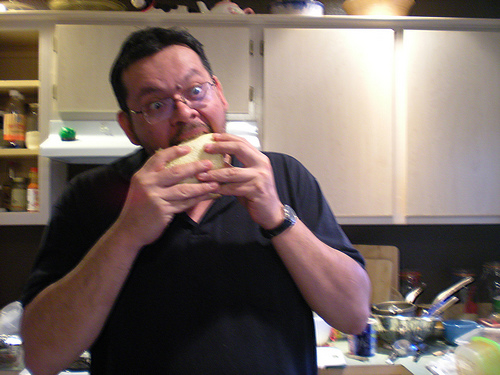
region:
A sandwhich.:
[152, 135, 231, 185]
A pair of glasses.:
[120, 82, 224, 122]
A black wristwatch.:
[261, 202, 299, 247]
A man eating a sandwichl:
[21, 25, 385, 374]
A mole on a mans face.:
[173, 79, 184, 93]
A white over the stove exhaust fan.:
[37, 117, 264, 165]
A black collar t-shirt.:
[24, 145, 366, 373]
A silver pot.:
[371, 280, 425, 315]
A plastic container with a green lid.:
[450, 334, 497, 369]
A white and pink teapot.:
[194, 2, 256, 19]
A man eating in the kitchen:
[6, 10, 493, 363]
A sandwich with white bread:
[160, 132, 230, 194]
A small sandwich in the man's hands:
[137, 124, 279, 206]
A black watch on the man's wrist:
[251, 200, 301, 250]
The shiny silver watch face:
[284, 203, 299, 224]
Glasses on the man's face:
[133, 87, 227, 121]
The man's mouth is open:
[163, 128, 211, 149]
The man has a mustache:
[165, 121, 216, 141]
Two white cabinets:
[260, 30, 480, 219]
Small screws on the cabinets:
[243, 37, 268, 99]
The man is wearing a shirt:
[30, 144, 366, 371]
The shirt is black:
[27, 152, 364, 373]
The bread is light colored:
[162, 131, 237, 193]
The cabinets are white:
[257, 10, 496, 214]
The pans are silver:
[375, 277, 472, 347]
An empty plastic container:
[460, 334, 497, 371]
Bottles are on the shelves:
[0, 87, 41, 212]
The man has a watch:
[259, 200, 298, 240]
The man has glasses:
[117, 77, 226, 123]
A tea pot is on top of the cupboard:
[197, 2, 253, 17]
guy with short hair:
[30, 18, 386, 370]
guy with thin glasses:
[15, 15, 390, 370]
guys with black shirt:
[35, 22, 350, 357]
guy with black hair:
[43, 14, 352, 374]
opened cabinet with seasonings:
[0, 20, 50, 224]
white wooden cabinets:
[255, 23, 495, 221]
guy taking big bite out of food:
[31, 28, 371, 370]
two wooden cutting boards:
[343, 235, 419, 320]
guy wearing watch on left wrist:
[36, 35, 386, 372]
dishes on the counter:
[364, 261, 499, 372]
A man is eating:
[25, 26, 367, 371]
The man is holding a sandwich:
[133, 132, 279, 197]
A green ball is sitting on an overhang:
[59, 126, 76, 139]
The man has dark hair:
[110, 28, 214, 119]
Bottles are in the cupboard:
[3, 84, 40, 214]